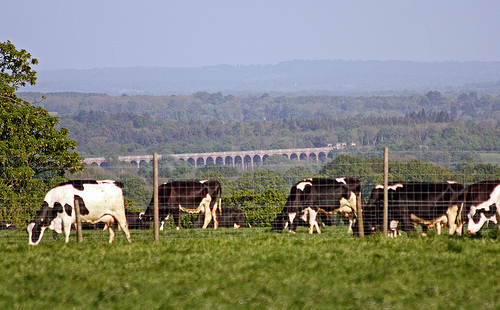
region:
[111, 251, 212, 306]
grass in front of cow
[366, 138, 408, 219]
pole above ground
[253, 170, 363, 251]
black and white cow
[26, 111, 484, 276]
many cows eating grass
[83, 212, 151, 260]
back legs of cow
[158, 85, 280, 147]
trees behind the cows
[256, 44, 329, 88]
fog in the distance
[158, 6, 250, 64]
sky above the land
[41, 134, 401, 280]
cows behind the fence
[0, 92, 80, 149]
tree next to the cows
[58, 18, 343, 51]
Sky is blue color.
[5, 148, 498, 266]
Cows are grassing.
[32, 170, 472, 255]
Cows are black and white color.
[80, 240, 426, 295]
Grass is green color.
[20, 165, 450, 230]
Fence is wire type.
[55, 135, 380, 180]
Bridge is brown color.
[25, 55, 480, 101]
Hill is seen behind the cow.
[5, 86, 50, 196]
Trees are green color.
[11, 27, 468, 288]
Day time picture.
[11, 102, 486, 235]
Trees are green color.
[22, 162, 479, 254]
many cows are grazing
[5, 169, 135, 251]
a black and white cow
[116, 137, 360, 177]
a highway in the distance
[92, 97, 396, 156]
green bushy trees behind the cows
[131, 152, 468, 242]
a fence with poles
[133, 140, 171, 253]
the poles are made of wood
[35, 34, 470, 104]
mountains in the far distance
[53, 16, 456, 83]
fog is in the air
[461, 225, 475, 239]
the cow`s nose is pink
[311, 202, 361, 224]
the cow has utters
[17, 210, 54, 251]
the head of a cow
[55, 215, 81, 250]
the front leg of a cow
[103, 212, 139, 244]
the hind legs of a cow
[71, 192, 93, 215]
a black spot on the cow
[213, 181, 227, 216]
the tail of a cow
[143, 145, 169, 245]
a wooden fence post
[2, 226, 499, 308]
a grassy green field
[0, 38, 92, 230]
a leafy green tree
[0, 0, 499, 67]
a clear blue sky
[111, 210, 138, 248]
the hind leg of a cow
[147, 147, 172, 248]
a brown wooden fence post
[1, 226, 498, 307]
a green grassy field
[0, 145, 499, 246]
a wire fence